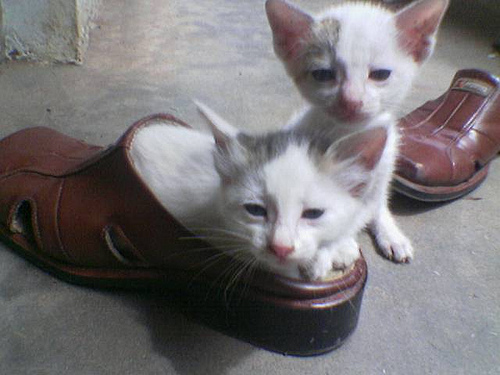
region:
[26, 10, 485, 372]
photograph of two white kittens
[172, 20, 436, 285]
two small white kittens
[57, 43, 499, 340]
two brown shoes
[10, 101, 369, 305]
kitten sitting in brown shoe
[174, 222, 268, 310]
white kitten whiskars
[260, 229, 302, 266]
small pink kitten nose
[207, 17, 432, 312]
two kittens looking directly at camera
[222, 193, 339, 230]
kitten with black eyes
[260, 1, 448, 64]
kitten with large ears that are pink inside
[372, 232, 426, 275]
white paw with nails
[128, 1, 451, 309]
two very small kittens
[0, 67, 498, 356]
a pair of brown clogs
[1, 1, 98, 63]
the bottom corner of a wall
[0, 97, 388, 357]
kitten is sitting inside a shoe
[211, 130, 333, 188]
kitten's fur is grey towards the top of its head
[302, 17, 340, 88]
patch of dark fur above kitten's left eye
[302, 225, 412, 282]
both of kittens' visible feet are white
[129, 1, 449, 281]
kittens' heads appear large in proportion to their bodies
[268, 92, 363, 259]
kittens' noses are pink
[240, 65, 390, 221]
kittens' eyes appear dark blue at this age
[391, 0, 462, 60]
left ear on cat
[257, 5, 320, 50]
right ear on cat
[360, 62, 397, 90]
the cat's left eye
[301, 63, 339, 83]
right eye of the cat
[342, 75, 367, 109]
nose on the cat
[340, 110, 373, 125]
the mouth of the cat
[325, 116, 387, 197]
the cat's left ear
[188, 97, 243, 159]
the cat's right ear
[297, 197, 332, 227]
the white cat's left eye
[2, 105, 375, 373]
brown sandal on floor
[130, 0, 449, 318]
the two white kittens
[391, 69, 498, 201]
the shiny brown shoe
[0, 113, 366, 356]
the brown shoe with a kitten in it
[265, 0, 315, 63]
the pink ear on the kitten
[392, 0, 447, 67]
the pink ear on the kitten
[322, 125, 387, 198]
the pink ear on the kitten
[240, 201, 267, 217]
the eye on the kitten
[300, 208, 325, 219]
the eye on the kitten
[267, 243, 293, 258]
the pink nose on the kitten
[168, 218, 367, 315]
the whiskers on the kitten's face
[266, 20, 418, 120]
face of the cat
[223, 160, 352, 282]
another face of the cat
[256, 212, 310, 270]
nose of the cat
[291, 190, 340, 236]
eye of the cat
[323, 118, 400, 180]
ear of the cat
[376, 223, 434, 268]
leg of the cat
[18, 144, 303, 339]
a shoe in the floor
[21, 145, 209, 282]
a shoe in the ground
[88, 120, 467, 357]
a cat inside the shoe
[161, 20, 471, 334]
two cats in ground